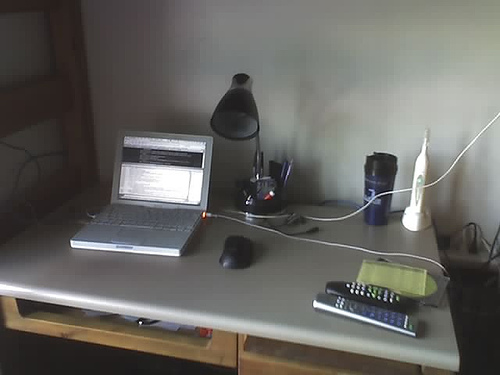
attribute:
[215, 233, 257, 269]
mouse — black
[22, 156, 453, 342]
table — large, silver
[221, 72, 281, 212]
lamp — black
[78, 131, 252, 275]
laptop — silver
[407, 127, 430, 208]
toothbrush — electric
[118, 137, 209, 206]
screen — glowing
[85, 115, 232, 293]
laptop — small, silver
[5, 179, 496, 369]
desk — small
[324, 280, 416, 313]
remote — black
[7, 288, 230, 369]
drawer — open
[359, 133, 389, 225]
thermos — blue, black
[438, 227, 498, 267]
power strip — white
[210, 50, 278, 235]
lamp — black, tabletop